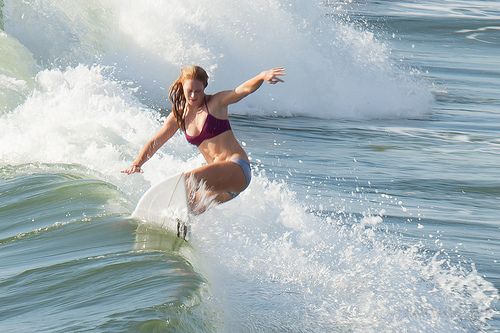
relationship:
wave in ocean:
[15, 63, 482, 331] [0, 2, 497, 330]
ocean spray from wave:
[1, 5, 445, 127] [0, 4, 500, 327]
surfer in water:
[123, 64, 286, 240] [324, 57, 464, 194]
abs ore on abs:
[208, 140, 225, 160] [199, 140, 225, 163]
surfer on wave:
[122, 64, 286, 240] [111, 214, 287, 331]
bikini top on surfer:
[181, 95, 230, 147] [119, 63, 285, 216]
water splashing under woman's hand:
[33, 109, 134, 205] [114, 156, 147, 184]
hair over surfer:
[167, 64, 209, 131] [122, 64, 286, 240]